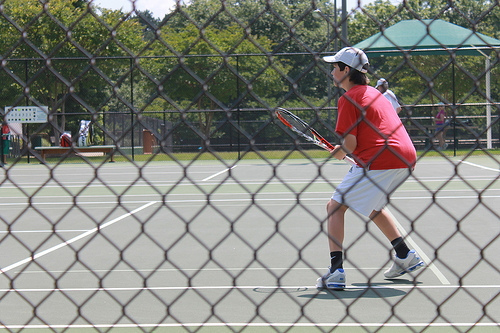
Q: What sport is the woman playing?
A: Tennis.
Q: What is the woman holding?
A: Tennis racket.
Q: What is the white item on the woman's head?
A: Hat.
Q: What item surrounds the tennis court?
A: Chainlink fence.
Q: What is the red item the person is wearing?
A: Shirt.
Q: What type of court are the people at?
A: Tennis.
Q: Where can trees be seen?
A: Background.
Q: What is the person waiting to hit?
A: Tennis ball.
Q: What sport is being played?
A: Tennis.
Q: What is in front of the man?
A: Fence.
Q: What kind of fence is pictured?
A: Chain link.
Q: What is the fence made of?
A: Metal.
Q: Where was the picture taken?
A: Tennis court.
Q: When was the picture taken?
A: Summer.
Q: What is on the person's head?
A: Hat.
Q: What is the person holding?
A: Tennis Racket.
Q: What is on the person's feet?
A: Tennis shoes.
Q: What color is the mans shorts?
A: White.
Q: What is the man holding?
A: A racket.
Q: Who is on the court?
A: A man.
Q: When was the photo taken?
A: Day time.